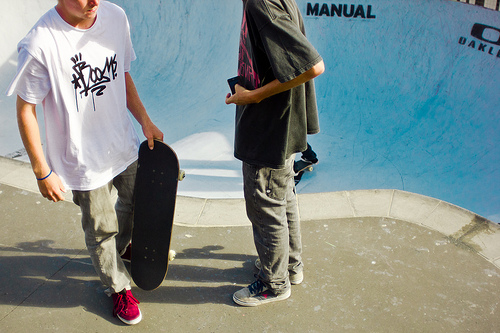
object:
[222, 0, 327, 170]
shirt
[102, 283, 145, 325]
shoe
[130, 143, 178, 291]
skateboard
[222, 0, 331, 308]
boy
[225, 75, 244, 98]
phone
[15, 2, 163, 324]
man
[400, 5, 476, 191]
ramp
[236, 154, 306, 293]
pants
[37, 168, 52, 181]
bracelet